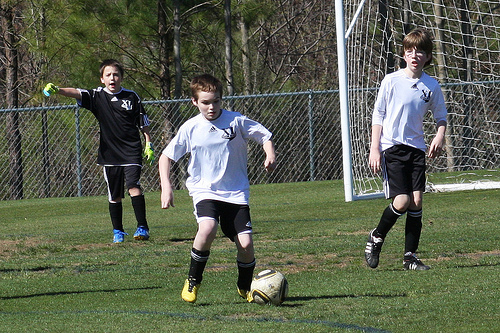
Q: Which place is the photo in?
A: It is at the field.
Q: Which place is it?
A: It is a field.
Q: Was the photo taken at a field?
A: Yes, it was taken in a field.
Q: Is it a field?
A: Yes, it is a field.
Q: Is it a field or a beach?
A: It is a field.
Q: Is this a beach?
A: No, it is a field.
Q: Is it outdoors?
A: Yes, it is outdoors.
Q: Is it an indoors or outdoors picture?
A: It is outdoors.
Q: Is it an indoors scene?
A: No, it is outdoors.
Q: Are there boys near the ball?
A: Yes, there is a boy near the ball.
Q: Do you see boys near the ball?
A: Yes, there is a boy near the ball.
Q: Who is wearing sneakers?
A: The boy is wearing sneakers.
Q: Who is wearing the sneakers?
A: The boy is wearing sneakers.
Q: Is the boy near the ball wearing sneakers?
A: Yes, the boy is wearing sneakers.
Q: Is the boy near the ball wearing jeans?
A: No, the boy is wearing sneakers.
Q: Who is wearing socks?
A: The boy is wearing socks.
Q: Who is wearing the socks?
A: The boy is wearing socks.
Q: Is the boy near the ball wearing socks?
A: Yes, the boy is wearing socks.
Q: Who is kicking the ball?
A: The boy is kicking the ball.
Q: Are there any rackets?
A: No, there are no rackets.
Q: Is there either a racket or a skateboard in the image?
A: No, there are no rackets or skateboards.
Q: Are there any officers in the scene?
A: No, there are no officers.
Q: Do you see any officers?
A: No, there are no officers.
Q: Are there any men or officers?
A: No, there are no officers or men.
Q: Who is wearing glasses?
A: The boy is wearing glasses.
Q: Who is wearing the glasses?
A: The boy is wearing glasses.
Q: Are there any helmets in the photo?
A: No, there are no helmets.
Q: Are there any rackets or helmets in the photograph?
A: No, there are no helmets or rackets.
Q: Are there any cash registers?
A: No, there are no cash registers.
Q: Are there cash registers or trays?
A: No, there are no cash registers or trays.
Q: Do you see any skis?
A: No, there are no skis.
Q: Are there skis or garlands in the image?
A: No, there are no skis or garlands.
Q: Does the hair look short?
A: Yes, the hair is short.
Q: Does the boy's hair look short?
A: Yes, the hair is short.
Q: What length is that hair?
A: The hair is short.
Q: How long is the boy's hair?
A: The hair is short.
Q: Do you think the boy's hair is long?
A: No, the hair is short.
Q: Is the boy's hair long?
A: No, the hair is short.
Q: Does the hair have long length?
A: No, the hair is short.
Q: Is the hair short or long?
A: The hair is short.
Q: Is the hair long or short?
A: The hair is short.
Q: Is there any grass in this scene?
A: Yes, there is grass.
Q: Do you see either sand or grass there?
A: Yes, there is grass.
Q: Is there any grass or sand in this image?
A: Yes, there is grass.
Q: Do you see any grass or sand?
A: Yes, there is grass.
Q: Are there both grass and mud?
A: No, there is grass but no mud.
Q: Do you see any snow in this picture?
A: No, there is no snow.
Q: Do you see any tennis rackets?
A: No, there are no tennis rackets.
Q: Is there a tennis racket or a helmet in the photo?
A: No, there are no rackets or helmets.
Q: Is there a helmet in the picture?
A: No, there are no helmets.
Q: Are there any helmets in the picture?
A: No, there are no helmets.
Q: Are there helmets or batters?
A: No, there are no helmets or batters.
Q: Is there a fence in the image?
A: Yes, there is a fence.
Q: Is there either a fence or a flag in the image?
A: Yes, there is a fence.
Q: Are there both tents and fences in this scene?
A: No, there is a fence but no tents.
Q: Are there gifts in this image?
A: No, there are no gifts.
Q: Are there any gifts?
A: No, there are no gifts.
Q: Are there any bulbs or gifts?
A: No, there are no gifts or bulbs.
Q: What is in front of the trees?
A: The fence is in front of the trees.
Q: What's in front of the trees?
A: The fence is in front of the trees.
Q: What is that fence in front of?
A: The fence is in front of the trees.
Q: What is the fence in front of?
A: The fence is in front of the trees.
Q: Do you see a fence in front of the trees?
A: Yes, there is a fence in front of the trees.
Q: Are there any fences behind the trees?
A: No, the fence is in front of the trees.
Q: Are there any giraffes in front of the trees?
A: No, there is a fence in front of the trees.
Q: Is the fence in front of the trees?
A: Yes, the fence is in front of the trees.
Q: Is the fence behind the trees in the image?
A: No, the fence is in front of the trees.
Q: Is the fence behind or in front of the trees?
A: The fence is in front of the trees.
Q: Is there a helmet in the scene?
A: No, there are no helmets.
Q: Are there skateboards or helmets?
A: No, there are no helmets or skateboards.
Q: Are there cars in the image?
A: No, there are no cars.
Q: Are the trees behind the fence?
A: Yes, the trees are behind the fence.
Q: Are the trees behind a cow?
A: No, the trees are behind the fence.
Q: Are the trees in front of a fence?
A: No, the trees are behind a fence.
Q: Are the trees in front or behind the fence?
A: The trees are behind the fence.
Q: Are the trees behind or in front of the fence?
A: The trees are behind the fence.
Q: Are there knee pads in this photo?
A: No, there are no knee pads.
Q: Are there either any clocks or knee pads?
A: No, there are no knee pads or clocks.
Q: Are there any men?
A: No, there are no men.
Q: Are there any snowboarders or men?
A: No, there are no men or snowboarders.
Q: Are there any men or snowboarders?
A: No, there are no men or snowboarders.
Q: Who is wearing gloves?
A: The boy is wearing gloves.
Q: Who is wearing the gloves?
A: The boy is wearing gloves.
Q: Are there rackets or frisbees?
A: No, there are no rackets or frisbees.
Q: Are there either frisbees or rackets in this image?
A: No, there are no rackets or frisbees.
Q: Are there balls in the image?
A: Yes, there is a ball.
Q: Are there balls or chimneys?
A: Yes, there is a ball.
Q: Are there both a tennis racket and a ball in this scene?
A: No, there is a ball but no rackets.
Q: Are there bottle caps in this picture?
A: No, there are no bottle caps.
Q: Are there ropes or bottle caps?
A: No, there are no bottle caps or ropes.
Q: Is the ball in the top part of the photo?
A: No, the ball is in the bottom of the image.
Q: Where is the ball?
A: The ball is on the grass.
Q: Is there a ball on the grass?
A: Yes, there is a ball on the grass.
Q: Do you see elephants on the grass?
A: No, there is a ball on the grass.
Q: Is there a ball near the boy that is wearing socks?
A: Yes, there is a ball near the boy.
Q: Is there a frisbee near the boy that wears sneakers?
A: No, there is a ball near the boy.